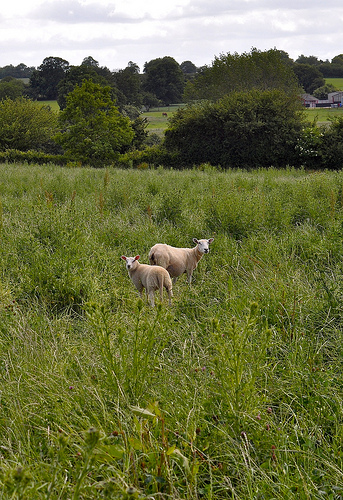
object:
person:
[170, 94, 286, 138]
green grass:
[103, 377, 239, 480]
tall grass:
[101, 372, 173, 477]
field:
[0, 161, 341, 498]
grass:
[1, 101, 343, 496]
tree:
[314, 111, 342, 173]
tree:
[160, 85, 317, 171]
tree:
[48, 73, 137, 170]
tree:
[1, 90, 65, 166]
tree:
[178, 43, 307, 109]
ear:
[132, 255, 141, 263]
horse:
[160, 110, 167, 116]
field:
[150, 104, 176, 139]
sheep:
[148, 238, 213, 287]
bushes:
[195, 194, 294, 228]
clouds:
[2, 2, 342, 49]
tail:
[159, 268, 176, 307]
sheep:
[121, 254, 175, 306]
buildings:
[293, 79, 342, 113]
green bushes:
[4, 150, 82, 172]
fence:
[128, 94, 184, 115]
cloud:
[1, 2, 342, 54]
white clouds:
[100, 11, 151, 43]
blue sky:
[0, 0, 342, 41]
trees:
[292, 49, 332, 93]